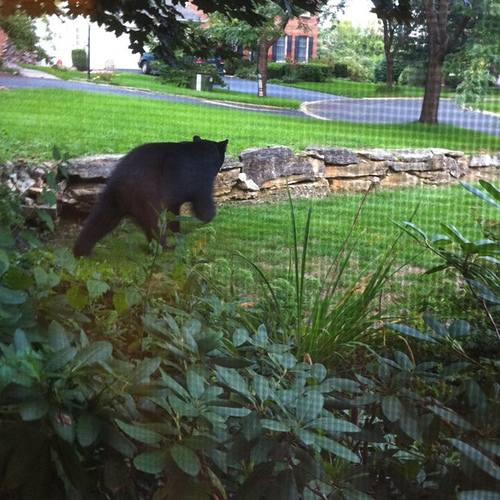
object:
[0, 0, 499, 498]
photo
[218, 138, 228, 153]
ears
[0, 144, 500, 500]
leaf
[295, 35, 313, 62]
window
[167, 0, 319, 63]
building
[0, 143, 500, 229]
rocks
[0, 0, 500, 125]
tree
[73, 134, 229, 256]
bear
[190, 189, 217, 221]
leg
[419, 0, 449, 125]
trunk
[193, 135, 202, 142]
ear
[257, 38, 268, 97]
trunk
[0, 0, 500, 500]
daytime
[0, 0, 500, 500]
plants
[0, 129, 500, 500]
foreground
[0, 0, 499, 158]
background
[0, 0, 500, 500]
landscaping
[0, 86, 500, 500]
wild